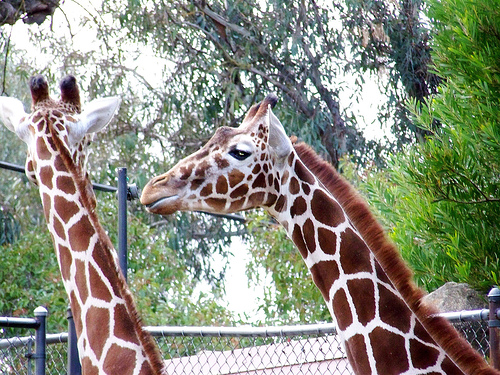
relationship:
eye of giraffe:
[214, 136, 255, 170] [133, 95, 484, 373]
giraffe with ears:
[4, 68, 167, 373] [1, 93, 121, 138]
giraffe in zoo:
[133, 95, 484, 373] [2, 0, 497, 374]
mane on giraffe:
[281, 126, 497, 371] [133, 95, 484, 373]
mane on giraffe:
[69, 205, 157, 332] [4, 68, 167, 373]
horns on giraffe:
[237, 88, 277, 126] [133, 95, 484, 373]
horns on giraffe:
[24, 66, 82, 109] [2, 52, 175, 372]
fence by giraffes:
[0, 310, 497, 374] [1, 66, 499, 373]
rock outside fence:
[416, 302, 465, 361] [278, 321, 330, 371]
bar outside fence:
[2, 161, 282, 235] [0, 310, 497, 374]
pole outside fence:
[111, 145, 134, 302] [0, 300, 482, 372]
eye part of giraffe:
[230, 148, 252, 159] [133, 95, 484, 373]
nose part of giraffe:
[105, 173, 177, 205] [133, 95, 484, 373]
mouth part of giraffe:
[142, 186, 192, 213] [133, 95, 484, 373]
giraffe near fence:
[133, 95, 484, 373] [2, 278, 481, 373]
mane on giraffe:
[290, 135, 499, 374] [125, 43, 485, 365]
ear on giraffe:
[69, 88, 122, 140] [128, 94, 440, 372]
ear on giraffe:
[0, 91, 33, 136] [128, 94, 440, 372]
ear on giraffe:
[254, 102, 296, 167] [128, 94, 440, 372]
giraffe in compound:
[0, 76, 166, 374] [4, 70, 470, 361]